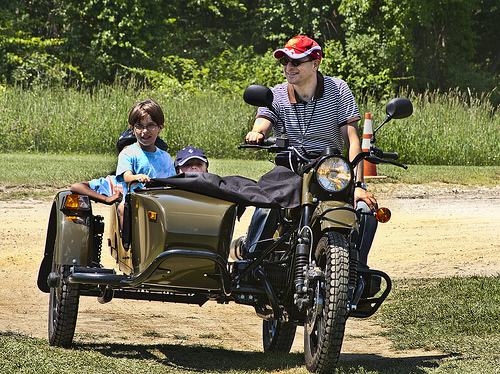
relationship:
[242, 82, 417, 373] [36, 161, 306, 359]
motorcycle has sidecar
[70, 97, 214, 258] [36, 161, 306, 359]
three children are in sidecar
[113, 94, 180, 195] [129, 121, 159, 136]
boy wears glasses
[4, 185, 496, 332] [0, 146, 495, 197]
road lined by grass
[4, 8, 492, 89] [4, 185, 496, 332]
trees are by road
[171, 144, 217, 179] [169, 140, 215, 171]
child wears cap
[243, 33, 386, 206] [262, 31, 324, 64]
man wears hat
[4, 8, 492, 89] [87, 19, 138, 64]
trees have green leaves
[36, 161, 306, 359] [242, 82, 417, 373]
sidecar of motorcycle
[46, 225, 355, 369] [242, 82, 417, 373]
three tires are on motorcycle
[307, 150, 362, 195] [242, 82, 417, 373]
headlight on motorcycle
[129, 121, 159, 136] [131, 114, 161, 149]
glasses are on face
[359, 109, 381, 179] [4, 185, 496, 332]
cone on side of road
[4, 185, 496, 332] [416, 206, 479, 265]
road made of dirt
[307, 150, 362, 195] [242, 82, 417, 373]
headlight on front of motorcycle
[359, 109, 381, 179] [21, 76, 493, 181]
cone in background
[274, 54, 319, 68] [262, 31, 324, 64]
sunglasses are with hat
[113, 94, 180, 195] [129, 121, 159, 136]
boy wearing glasses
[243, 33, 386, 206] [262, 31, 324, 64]
man has hat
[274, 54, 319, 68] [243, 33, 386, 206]
sunglasses are on man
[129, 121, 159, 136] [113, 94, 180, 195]
glasses are on boy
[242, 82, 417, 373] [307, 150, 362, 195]
motorcycle has headlight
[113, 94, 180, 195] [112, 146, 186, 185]
boy wears blue shirt